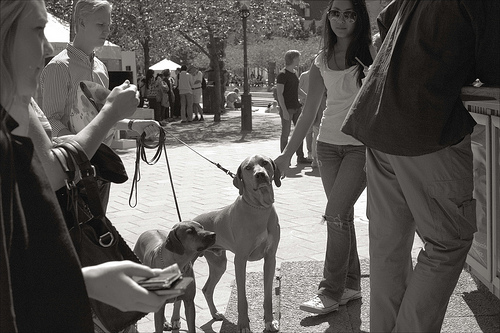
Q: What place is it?
A: It is a street.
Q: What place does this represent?
A: It represents the street.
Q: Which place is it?
A: It is a street.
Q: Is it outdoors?
A: Yes, it is outdoors.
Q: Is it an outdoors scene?
A: Yes, it is outdoors.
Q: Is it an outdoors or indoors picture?
A: It is outdoors.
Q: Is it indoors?
A: No, it is outdoors.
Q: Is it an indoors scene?
A: No, it is outdoors.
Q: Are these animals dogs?
A: Yes, all the animals are dogs.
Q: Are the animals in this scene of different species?
A: No, all the animals are dogs.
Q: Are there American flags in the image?
A: No, there are no American flags.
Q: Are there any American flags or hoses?
A: No, there are no American flags or hoses.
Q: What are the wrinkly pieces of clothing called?
A: The clothing items are jeans.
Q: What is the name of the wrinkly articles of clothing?
A: The clothing items are jeans.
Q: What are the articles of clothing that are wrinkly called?
A: The clothing items are jeans.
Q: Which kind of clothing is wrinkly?
A: The clothing is jeans.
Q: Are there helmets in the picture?
A: No, there are no helmets.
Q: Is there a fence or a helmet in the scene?
A: No, there are no helmets or fences.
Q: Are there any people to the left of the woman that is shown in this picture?
A: Yes, there is a person to the left of the woman.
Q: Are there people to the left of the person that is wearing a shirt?
A: Yes, there is a person to the left of the woman.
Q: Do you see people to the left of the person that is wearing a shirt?
A: Yes, there is a person to the left of the woman.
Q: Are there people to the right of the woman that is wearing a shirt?
A: No, the person is to the left of the woman.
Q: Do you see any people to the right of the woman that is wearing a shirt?
A: No, the person is to the left of the woman.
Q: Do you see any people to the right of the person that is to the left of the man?
A: No, the person is to the left of the woman.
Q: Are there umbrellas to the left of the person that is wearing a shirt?
A: No, there is a person to the left of the woman.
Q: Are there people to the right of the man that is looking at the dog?
A: Yes, there is a person to the right of the man.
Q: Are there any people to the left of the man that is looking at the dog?
A: No, the person is to the right of the man.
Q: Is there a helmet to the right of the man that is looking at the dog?
A: No, there is a person to the right of the man.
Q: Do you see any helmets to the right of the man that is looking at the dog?
A: No, there is a person to the right of the man.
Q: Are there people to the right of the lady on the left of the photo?
A: Yes, there is a person to the right of the lady.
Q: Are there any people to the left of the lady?
A: No, the person is to the right of the lady.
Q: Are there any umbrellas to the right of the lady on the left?
A: No, there is a person to the right of the lady.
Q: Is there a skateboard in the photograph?
A: No, there are no skateboards.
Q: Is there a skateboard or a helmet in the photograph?
A: No, there are no skateboards or helmets.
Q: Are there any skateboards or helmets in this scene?
A: No, there are no skateboards or helmets.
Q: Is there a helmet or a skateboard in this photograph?
A: No, there are no skateboards or helmets.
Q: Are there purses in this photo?
A: Yes, there is a purse.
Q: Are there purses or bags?
A: Yes, there is a purse.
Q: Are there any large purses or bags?
A: Yes, there is a large purse.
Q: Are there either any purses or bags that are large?
A: Yes, the purse is large.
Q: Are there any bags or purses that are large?
A: Yes, the purse is large.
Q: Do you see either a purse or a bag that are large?
A: Yes, the purse is large.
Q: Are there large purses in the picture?
A: Yes, there is a large purse.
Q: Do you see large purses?
A: Yes, there is a large purse.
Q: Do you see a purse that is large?
A: Yes, there is a purse that is large.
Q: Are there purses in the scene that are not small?
A: Yes, there is a large purse.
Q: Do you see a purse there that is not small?
A: Yes, there is a large purse.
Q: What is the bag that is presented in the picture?
A: The bag is a purse.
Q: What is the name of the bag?
A: The bag is a purse.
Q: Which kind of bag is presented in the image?
A: The bag is a purse.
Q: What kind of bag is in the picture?
A: The bag is a purse.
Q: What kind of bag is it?
A: The bag is a purse.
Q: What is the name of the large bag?
A: The bag is a purse.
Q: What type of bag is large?
A: The bag is a purse.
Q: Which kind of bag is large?
A: The bag is a purse.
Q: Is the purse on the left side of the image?
A: Yes, the purse is on the left of the image.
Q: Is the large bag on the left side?
A: Yes, the purse is on the left of the image.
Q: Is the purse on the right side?
A: No, the purse is on the left of the image.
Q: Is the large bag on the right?
A: No, the purse is on the left of the image.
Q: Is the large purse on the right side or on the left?
A: The purse is on the left of the image.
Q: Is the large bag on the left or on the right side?
A: The purse is on the left of the image.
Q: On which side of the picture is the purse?
A: The purse is on the left of the image.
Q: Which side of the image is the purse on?
A: The purse is on the left of the image.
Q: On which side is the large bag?
A: The purse is on the left of the image.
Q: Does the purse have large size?
A: Yes, the purse is large.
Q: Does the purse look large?
A: Yes, the purse is large.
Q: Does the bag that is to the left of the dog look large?
A: Yes, the purse is large.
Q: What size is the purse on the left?
A: The purse is large.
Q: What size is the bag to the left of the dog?
A: The purse is large.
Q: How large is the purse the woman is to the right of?
A: The purse is large.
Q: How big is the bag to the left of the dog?
A: The purse is large.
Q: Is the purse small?
A: No, the purse is large.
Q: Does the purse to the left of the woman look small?
A: No, the purse is large.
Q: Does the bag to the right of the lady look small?
A: No, the purse is large.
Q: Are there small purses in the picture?
A: No, there is a purse but it is large.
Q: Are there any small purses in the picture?
A: No, there is a purse but it is large.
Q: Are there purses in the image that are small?
A: No, there is a purse but it is large.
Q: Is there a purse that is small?
A: No, there is a purse but it is large.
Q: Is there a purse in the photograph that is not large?
A: No, there is a purse but it is large.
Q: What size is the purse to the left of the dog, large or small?
A: The purse is large.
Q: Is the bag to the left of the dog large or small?
A: The purse is large.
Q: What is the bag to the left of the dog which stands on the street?
A: The bag is a purse.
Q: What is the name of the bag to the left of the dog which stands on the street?
A: The bag is a purse.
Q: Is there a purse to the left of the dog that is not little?
A: Yes, there is a purse to the left of the dog.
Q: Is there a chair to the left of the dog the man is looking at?
A: No, there is a purse to the left of the dog.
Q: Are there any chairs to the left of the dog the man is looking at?
A: No, there is a purse to the left of the dog.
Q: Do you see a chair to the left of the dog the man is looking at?
A: No, there is a purse to the left of the dog.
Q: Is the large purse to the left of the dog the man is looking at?
A: Yes, the purse is to the left of the dog.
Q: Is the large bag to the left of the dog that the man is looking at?
A: Yes, the purse is to the left of the dog.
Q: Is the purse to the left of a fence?
A: No, the purse is to the left of the dog.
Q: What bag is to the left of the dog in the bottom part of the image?
A: The bag is a purse.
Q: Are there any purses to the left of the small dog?
A: Yes, there is a purse to the left of the dog.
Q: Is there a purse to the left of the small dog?
A: Yes, there is a purse to the left of the dog.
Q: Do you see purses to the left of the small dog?
A: Yes, there is a purse to the left of the dog.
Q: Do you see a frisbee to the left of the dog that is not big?
A: No, there is a purse to the left of the dog.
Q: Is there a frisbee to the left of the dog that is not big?
A: No, there is a purse to the left of the dog.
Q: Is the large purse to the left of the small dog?
A: Yes, the purse is to the left of the dog.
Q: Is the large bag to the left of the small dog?
A: Yes, the purse is to the left of the dog.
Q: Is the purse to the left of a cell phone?
A: No, the purse is to the left of the dog.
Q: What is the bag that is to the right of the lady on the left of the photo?
A: The bag is a purse.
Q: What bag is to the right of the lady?
A: The bag is a purse.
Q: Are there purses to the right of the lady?
A: Yes, there is a purse to the right of the lady.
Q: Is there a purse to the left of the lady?
A: No, the purse is to the right of the lady.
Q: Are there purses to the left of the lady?
A: No, the purse is to the right of the lady.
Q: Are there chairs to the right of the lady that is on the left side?
A: No, there is a purse to the right of the lady.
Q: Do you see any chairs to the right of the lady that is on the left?
A: No, there is a purse to the right of the lady.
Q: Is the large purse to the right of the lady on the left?
A: Yes, the purse is to the right of the lady.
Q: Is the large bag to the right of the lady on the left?
A: Yes, the purse is to the right of the lady.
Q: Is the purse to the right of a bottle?
A: No, the purse is to the right of the lady.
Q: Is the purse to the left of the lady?
A: No, the purse is to the right of the lady.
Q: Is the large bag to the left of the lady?
A: No, the purse is to the right of the lady.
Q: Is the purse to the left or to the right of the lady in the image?
A: The purse is to the right of the lady.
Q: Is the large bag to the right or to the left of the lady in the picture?
A: The purse is to the right of the lady.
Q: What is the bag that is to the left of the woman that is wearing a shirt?
A: The bag is a purse.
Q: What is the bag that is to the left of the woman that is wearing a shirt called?
A: The bag is a purse.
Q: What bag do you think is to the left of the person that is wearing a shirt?
A: The bag is a purse.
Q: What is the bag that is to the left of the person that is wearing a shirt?
A: The bag is a purse.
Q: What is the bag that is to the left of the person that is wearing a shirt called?
A: The bag is a purse.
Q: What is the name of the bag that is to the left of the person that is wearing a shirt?
A: The bag is a purse.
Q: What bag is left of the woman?
A: The bag is a purse.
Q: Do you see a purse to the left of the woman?
A: Yes, there is a purse to the left of the woman.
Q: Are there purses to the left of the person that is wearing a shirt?
A: Yes, there is a purse to the left of the woman.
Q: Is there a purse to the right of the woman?
A: No, the purse is to the left of the woman.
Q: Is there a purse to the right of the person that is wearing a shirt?
A: No, the purse is to the left of the woman.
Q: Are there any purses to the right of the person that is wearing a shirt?
A: No, the purse is to the left of the woman.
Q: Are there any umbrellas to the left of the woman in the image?
A: No, there is a purse to the left of the woman.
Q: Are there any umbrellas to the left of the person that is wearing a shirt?
A: No, there is a purse to the left of the woman.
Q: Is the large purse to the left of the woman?
A: Yes, the purse is to the left of the woman.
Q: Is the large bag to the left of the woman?
A: Yes, the purse is to the left of the woman.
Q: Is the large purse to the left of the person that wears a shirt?
A: Yes, the purse is to the left of the woman.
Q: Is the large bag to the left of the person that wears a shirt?
A: Yes, the purse is to the left of the woman.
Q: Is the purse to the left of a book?
A: No, the purse is to the left of the woman.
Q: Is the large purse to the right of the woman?
A: No, the purse is to the left of the woman.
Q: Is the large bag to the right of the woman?
A: No, the purse is to the left of the woman.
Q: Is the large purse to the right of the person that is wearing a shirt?
A: No, the purse is to the left of the woman.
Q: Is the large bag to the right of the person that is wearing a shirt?
A: No, the purse is to the left of the woman.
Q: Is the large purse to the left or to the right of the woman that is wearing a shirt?
A: The purse is to the left of the woman.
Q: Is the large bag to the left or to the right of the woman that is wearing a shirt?
A: The purse is to the left of the woman.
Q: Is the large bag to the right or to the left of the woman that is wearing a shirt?
A: The purse is to the left of the woman.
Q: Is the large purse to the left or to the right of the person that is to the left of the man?
A: The purse is to the left of the woman.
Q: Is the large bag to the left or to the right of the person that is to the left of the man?
A: The purse is to the left of the woman.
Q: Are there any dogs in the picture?
A: Yes, there is a dog.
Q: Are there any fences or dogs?
A: Yes, there is a dog.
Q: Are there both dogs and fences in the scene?
A: No, there is a dog but no fences.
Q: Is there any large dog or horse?
A: Yes, there is a large dog.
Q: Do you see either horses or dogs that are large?
A: Yes, the dog is large.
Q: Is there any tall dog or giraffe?
A: Yes, there is a tall dog.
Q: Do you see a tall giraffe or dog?
A: Yes, there is a tall dog.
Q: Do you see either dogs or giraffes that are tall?
A: Yes, the dog is tall.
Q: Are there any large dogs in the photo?
A: Yes, there is a large dog.